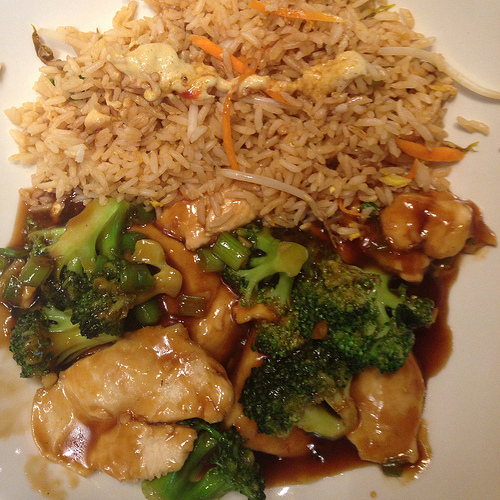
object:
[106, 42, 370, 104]
egg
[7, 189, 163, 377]
broccoli pieces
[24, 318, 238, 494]
piece of chicken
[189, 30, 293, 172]
carrots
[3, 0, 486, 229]
rice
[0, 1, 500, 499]
plate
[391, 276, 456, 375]
sauce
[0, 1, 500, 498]
food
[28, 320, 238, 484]
chicken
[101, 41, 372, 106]
small piece of egg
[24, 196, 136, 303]
stem of broccoli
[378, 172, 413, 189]
something yellow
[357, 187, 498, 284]
meat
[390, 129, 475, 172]
pieces of carrot